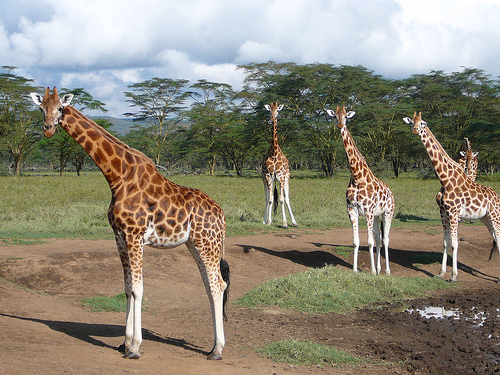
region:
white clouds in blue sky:
[1, 1, 79, 42]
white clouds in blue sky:
[94, 36, 129, 61]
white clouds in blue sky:
[37, 32, 62, 46]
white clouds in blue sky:
[115, 21, 150, 48]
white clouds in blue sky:
[144, 23, 186, 57]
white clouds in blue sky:
[230, 5, 260, 26]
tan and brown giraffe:
[21, 78, 241, 358]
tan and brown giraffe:
[253, 90, 304, 231]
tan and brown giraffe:
[307, 87, 397, 282]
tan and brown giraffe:
[398, 69, 498, 273]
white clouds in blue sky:
[31, 8, 101, 42]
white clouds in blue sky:
[435, 23, 497, 65]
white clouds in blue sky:
[374, 8, 456, 53]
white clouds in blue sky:
[295, 13, 362, 41]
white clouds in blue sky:
[210, 13, 267, 33]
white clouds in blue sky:
[165, 10, 205, 45]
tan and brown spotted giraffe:
[16, 70, 229, 360]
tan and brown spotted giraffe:
[240, 85, 306, 241]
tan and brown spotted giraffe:
[313, 92, 393, 259]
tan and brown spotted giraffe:
[387, 92, 471, 270]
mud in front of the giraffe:
[351, 288, 486, 355]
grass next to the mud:
[270, 261, 395, 314]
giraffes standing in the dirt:
[23, 83, 497, 355]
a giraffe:
[33, 92, 235, 348]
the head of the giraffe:
[33, 92, 74, 137]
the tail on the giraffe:
[216, 223, 232, 316]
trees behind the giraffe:
[12, 68, 484, 166]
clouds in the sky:
[13, 40, 473, 71]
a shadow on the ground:
[233, 235, 341, 270]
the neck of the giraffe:
[66, 113, 131, 178]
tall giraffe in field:
[14, 87, 241, 344]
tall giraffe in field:
[244, 122, 301, 210]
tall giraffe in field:
[332, 87, 412, 269]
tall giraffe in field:
[417, 122, 491, 270]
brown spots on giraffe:
[113, 167, 172, 215]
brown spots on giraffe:
[253, 148, 280, 178]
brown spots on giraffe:
[356, 167, 390, 198]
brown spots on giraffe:
[438, 173, 473, 210]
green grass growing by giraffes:
[285, 264, 347, 299]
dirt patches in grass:
[32, 227, 286, 353]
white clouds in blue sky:
[7, 17, 66, 44]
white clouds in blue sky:
[108, 24, 145, 44]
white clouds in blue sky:
[227, 15, 259, 34]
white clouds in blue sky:
[230, 4, 294, 51]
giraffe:
[252, 90, 301, 235]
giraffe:
[317, 99, 407, 279]